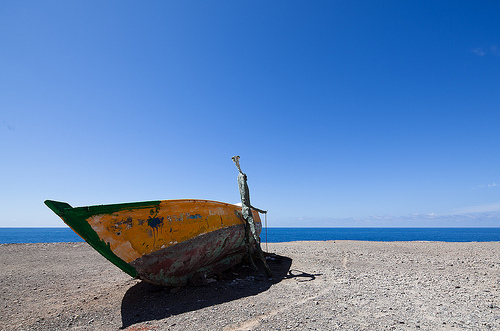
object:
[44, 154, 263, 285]
boat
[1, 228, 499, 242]
water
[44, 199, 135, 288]
edges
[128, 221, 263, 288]
rust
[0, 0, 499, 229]
sky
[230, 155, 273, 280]
object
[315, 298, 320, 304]
rock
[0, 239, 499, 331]
sand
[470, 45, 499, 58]
cloud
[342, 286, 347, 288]
rocks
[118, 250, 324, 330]
shadow